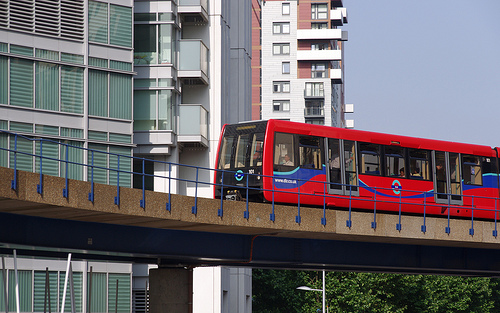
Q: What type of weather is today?
A: It is clear.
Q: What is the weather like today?
A: It is clear.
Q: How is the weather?
A: It is clear.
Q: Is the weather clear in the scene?
A: Yes, it is clear.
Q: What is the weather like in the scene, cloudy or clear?
A: It is clear.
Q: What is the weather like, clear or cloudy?
A: It is clear.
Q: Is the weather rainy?
A: No, it is clear.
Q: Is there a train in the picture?
A: Yes, there is a train.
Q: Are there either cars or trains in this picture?
A: Yes, there is a train.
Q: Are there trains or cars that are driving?
A: Yes, the train is driving.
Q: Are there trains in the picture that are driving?
A: Yes, there is a train that is driving.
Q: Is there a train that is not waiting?
A: Yes, there is a train that is driving.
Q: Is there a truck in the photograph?
A: No, there are no trucks.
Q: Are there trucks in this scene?
A: No, there are no trucks.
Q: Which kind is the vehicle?
A: The vehicle is a train.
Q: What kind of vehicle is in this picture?
A: The vehicle is a train.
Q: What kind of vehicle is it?
A: The vehicle is a train.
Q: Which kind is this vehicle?
A: This is a train.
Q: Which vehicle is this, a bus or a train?
A: This is a train.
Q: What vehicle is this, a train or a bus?
A: This is a train.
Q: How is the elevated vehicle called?
A: The vehicle is a train.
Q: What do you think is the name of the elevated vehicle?
A: The vehicle is a train.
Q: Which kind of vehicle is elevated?
A: The vehicle is a train.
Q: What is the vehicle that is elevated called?
A: The vehicle is a train.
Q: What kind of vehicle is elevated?
A: The vehicle is a train.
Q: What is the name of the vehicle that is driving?
A: The vehicle is a train.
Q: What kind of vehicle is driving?
A: The vehicle is a train.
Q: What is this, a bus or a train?
A: This is a train.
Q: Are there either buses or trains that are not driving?
A: No, there is a train but it is driving.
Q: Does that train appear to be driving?
A: Yes, the train is driving.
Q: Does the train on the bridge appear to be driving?
A: Yes, the train is driving.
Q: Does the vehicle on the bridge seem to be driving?
A: Yes, the train is driving.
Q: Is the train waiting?
A: No, the train is driving.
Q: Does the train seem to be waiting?
A: No, the train is driving.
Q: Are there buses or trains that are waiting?
A: No, there is a train but it is driving.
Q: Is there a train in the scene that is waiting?
A: No, there is a train but it is driving.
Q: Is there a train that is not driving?
A: No, there is a train but it is driving.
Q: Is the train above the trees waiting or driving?
A: The train is driving.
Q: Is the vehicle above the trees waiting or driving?
A: The train is driving.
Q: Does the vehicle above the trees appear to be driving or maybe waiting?
A: The train is driving.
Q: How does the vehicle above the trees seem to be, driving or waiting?
A: The train is driving.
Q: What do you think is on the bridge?
A: The train is on the bridge.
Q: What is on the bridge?
A: The train is on the bridge.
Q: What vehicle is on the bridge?
A: The vehicle is a train.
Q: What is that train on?
A: The train is on the bridge.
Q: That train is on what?
A: The train is on the bridge.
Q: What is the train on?
A: The train is on the bridge.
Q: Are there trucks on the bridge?
A: No, there is a train on the bridge.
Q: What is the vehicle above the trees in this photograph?
A: The vehicle is a train.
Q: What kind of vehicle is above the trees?
A: The vehicle is a train.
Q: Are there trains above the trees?
A: Yes, there is a train above the trees.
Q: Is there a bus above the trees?
A: No, there is a train above the trees.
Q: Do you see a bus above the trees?
A: No, there is a train above the trees.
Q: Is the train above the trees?
A: Yes, the train is above the trees.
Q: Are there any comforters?
A: No, there are no comforters.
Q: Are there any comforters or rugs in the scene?
A: No, there are no comforters or rugs.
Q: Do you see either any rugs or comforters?
A: No, there are no comforters or rugs.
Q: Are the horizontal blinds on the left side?
A: Yes, the blinds are on the left of the image.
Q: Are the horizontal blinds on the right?
A: No, the blinds are on the left of the image.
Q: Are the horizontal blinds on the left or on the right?
A: The blinds are on the left of the image.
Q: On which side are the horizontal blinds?
A: The blinds are on the left of the image.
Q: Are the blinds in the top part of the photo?
A: Yes, the blinds are in the top of the image.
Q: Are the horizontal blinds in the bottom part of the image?
A: No, the blinds are in the top of the image.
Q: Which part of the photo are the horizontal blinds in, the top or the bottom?
A: The blinds are in the top of the image.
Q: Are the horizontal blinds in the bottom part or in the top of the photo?
A: The blinds are in the top of the image.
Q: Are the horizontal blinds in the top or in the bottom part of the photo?
A: The blinds are in the top of the image.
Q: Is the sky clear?
A: Yes, the sky is clear.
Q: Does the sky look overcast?
A: No, the sky is clear.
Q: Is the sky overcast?
A: No, the sky is clear.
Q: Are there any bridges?
A: Yes, there is a bridge.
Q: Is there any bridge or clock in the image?
A: Yes, there is a bridge.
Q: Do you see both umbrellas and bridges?
A: No, there is a bridge but no umbrellas.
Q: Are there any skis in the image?
A: No, there are no skis.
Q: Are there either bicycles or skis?
A: No, there are no skis or bicycles.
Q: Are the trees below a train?
A: Yes, the trees are below a train.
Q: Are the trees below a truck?
A: No, the trees are below a train.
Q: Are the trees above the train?
A: No, the trees are below the train.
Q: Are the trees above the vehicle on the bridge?
A: No, the trees are below the train.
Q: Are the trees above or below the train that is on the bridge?
A: The trees are below the train.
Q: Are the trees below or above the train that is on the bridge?
A: The trees are below the train.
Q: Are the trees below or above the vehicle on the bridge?
A: The trees are below the train.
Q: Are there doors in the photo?
A: Yes, there are doors.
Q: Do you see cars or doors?
A: Yes, there are doors.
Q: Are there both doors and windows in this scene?
A: Yes, there are both doors and a window.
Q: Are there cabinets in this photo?
A: No, there are no cabinets.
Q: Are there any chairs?
A: No, there are no chairs.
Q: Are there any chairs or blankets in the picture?
A: No, there are no chairs or blankets.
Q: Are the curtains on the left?
A: Yes, the curtains are on the left of the image.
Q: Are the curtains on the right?
A: No, the curtains are on the left of the image.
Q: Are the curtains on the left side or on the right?
A: The curtains are on the left of the image.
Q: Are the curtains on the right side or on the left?
A: The curtains are on the left of the image.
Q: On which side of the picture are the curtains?
A: The curtains are on the left of the image.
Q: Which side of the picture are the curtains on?
A: The curtains are on the left of the image.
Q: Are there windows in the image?
A: Yes, there are windows.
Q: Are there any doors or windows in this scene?
A: Yes, there are windows.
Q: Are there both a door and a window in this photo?
A: Yes, there are both a window and a door.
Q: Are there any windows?
A: Yes, there are windows.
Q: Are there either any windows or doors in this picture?
A: Yes, there are windows.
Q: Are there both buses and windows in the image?
A: No, there are windows but no buses.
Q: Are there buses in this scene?
A: No, there are no buses.